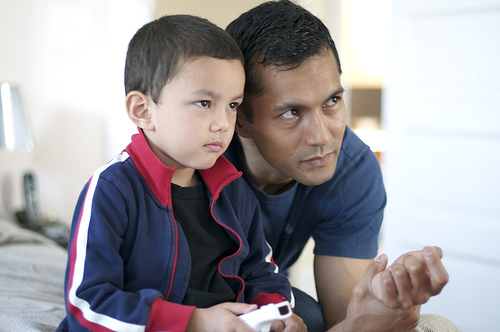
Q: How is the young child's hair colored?
A: Brunette.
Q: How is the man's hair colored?
A: Black.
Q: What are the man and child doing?
A: Playing wii.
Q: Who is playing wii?
A: The little boy.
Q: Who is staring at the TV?
A: The man.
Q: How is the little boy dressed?
A: Blue and red sweatshirt.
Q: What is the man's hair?
A: Dark.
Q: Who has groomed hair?
A: The man.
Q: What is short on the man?
A: Hair.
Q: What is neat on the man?
A: Hair.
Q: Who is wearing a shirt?
A: The man.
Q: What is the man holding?
A: Wrist.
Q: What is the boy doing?
A: Sitting.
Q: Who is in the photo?
A: Two people.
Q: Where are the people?
A: In a room.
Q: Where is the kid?
A: Next to the man.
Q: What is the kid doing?
A: Sitting down.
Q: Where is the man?
A: Next to the kid.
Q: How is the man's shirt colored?
A: Blue.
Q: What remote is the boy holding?
A: Wii remote.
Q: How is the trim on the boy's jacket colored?
A: Red.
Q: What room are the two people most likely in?
A: A bedroom.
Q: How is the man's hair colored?
A: Black.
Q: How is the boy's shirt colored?
A: Black.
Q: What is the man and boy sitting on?
A: A bed.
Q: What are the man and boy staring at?
A: Television.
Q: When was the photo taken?
A: Daytime.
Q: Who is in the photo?
A: Two people.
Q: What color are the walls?
A: White.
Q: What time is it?
A: Daytime.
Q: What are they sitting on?
A: Bed.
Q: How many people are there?
A: Two.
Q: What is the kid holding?
A: A remote.